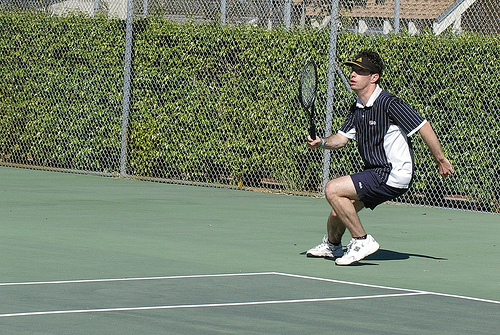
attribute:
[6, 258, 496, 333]
lines — white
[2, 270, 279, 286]
line — white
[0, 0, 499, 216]
fence — chain link, green , behind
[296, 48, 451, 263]
he — poised, ready, male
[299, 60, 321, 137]
racket — black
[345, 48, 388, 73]
hat — black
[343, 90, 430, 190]
shirt — black, white, striped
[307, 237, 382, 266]
shoes — white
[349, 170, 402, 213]
shorts — dark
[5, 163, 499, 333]
court — green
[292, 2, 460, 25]
roof — brown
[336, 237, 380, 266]
shoe — white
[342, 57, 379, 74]
visor — black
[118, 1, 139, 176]
pole — silver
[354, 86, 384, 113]
collar — white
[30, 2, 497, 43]
neighborhood — blocked